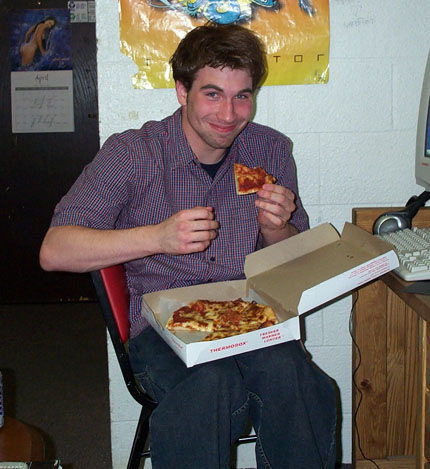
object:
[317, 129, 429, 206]
blocks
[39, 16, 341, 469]
man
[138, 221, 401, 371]
pizzabox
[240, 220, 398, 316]
lid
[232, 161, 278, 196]
pizza slice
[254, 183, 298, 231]
hand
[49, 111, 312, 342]
shirt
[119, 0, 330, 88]
poster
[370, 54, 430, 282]
computer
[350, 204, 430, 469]
desk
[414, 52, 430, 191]
monitor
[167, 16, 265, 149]
head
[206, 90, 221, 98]
eyes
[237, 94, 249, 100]
eyes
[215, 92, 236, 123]
nose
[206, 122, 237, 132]
mouth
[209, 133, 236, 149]
chin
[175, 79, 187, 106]
ear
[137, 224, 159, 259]
wrist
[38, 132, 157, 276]
arm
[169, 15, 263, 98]
hair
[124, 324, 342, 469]
jeans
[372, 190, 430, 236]
headphones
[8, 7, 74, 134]
calendar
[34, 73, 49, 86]
april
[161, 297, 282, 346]
pizza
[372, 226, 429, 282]
keyboard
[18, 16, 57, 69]
woman